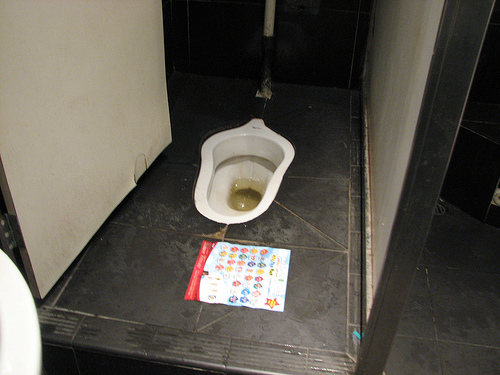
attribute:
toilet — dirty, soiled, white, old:
[195, 118, 294, 224]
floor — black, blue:
[31, 74, 362, 374]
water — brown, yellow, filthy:
[228, 178, 266, 210]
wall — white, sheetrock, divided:
[361, 3, 449, 318]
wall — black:
[169, 3, 371, 91]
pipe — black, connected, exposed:
[264, 7, 277, 90]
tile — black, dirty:
[263, 83, 351, 183]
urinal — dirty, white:
[193, 116, 295, 227]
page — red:
[181, 241, 216, 300]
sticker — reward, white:
[183, 238, 291, 314]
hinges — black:
[2, 215, 26, 254]